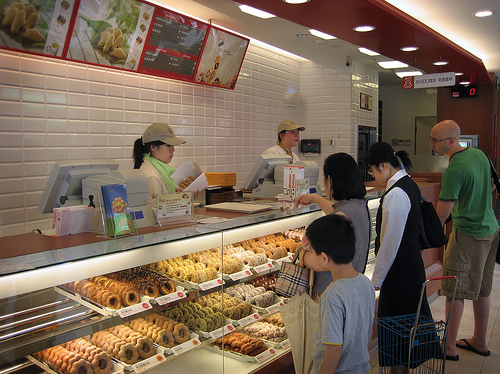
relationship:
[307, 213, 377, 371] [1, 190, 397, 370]
people standing in front doughnut display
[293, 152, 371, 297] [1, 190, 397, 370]
people standing in front doughnut display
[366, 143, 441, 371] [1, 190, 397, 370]
people standing in front doughnut display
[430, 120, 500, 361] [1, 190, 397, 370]
customer standing in front doughnut display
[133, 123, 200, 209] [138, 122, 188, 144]
girl wearing cap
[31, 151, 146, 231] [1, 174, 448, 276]
cash register behind counter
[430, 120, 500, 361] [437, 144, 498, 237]
customer wearing green shirt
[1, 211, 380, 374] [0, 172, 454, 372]
doughnut display in counter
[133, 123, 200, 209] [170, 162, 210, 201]
girl holding box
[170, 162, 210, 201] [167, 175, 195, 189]
box of doughnuts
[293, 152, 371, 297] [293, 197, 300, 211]
people points finger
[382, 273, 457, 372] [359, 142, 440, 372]
cart behind people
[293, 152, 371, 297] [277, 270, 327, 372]
people with umbrella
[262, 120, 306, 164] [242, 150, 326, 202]
girl at register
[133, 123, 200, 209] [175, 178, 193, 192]
girl holding doughnuts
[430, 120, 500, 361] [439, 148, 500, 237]
customer in green shirt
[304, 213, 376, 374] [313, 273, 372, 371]
boy in shirt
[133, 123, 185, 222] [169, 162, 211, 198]
girl holding box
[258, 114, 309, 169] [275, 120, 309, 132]
girl in hat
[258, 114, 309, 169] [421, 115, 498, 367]
girl helping customer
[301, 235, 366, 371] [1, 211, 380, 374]
boy staring at doughnut display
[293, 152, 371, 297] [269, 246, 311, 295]
people with white/pink/blue purse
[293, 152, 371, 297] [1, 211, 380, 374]
people ordering doughnut display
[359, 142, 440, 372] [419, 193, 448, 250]
people with purse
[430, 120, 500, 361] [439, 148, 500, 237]
customer wearing green shirt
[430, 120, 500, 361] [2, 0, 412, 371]
customer at donut shop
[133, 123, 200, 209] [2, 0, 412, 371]
girl at donut shop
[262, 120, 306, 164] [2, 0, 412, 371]
girl at donut shop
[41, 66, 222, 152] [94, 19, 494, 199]
tiles covering wall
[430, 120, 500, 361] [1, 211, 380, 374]
customer with doughnut display